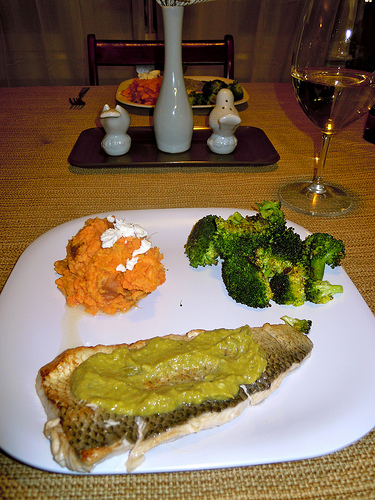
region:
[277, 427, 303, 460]
part of a plate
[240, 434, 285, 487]
edge of a plate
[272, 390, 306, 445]
part of a plate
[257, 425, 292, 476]
part of a plte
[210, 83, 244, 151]
A bird salt shaker.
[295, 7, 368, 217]
A glass of white wine.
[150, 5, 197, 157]
A white porcelain vase.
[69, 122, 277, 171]
A tray in middle of table.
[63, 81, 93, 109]
A fork on a table.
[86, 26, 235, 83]
A wooden brown chair.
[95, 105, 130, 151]
A procelain bird with head down.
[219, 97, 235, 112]
Holes on a salt and pepper shaker.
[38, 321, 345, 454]
A piece of fish on a plate.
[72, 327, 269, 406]
Sauce on a slice of fish.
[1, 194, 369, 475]
meal served on a white plate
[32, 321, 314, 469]
fish served with a mustard sauce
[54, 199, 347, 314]
broccoli and mashed potatoes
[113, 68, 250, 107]
another plate of food across the table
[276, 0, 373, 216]
half-full glass of wine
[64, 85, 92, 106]
fork on the tablecloth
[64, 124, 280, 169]
tray holding salt and pepper shakers and a vase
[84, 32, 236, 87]
chair at the end of the table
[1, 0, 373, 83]
curtains at the window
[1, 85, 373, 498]
table cloth on the table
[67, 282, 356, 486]
This is a filet of fish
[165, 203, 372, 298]
This is a bunch of broccoli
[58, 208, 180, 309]
This is smashed squash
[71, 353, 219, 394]
This is a green sauce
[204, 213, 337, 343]
The broccoli was roasted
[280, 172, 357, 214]
This is a glass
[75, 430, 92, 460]
The fish is white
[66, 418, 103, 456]
The fish has scales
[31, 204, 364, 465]
the plate is square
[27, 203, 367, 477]
the plate is white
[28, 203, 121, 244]
the edge of the plate is rounded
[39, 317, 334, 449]
fish on the plate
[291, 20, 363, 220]
glass of wine on the table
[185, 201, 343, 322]
the broccoli on the plate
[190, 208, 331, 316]
broccoli is roasted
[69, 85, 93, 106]
the fork on the table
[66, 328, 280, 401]
the green paste on the fish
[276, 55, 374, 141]
liquid in the glass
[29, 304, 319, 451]
sauce on the bread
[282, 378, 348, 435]
white plate under food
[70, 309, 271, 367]
side of the food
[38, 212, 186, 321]
orange food on plate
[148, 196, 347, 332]
broccoli on the plate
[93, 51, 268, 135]
plate on other side of table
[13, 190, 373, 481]
a white dinner plate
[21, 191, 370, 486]
a plate of food